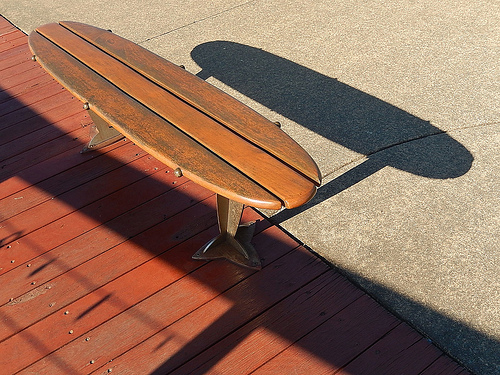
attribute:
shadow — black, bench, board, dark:
[214, 46, 455, 170]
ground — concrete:
[92, 15, 490, 270]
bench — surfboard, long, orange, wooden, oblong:
[42, 26, 317, 217]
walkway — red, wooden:
[25, 190, 341, 365]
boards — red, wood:
[12, 175, 111, 258]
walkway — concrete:
[203, 10, 482, 114]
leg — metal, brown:
[200, 215, 266, 269]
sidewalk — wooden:
[24, 213, 366, 374]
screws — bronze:
[73, 98, 96, 114]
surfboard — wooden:
[78, 50, 262, 168]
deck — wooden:
[101, 71, 185, 152]